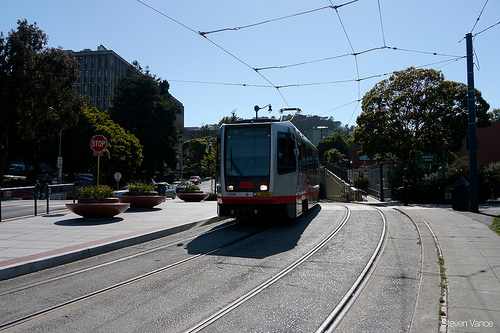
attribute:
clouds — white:
[170, 37, 237, 74]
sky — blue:
[121, 8, 496, 124]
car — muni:
[216, 118, 322, 220]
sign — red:
[92, 132, 106, 152]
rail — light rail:
[217, 111, 323, 226]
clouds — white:
[199, 100, 220, 110]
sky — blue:
[50, 5, 105, 34]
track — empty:
[185, 200, 387, 331]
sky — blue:
[46, 4, 498, 117]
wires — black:
[207, 7, 360, 77]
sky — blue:
[3, 0, 499, 127]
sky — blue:
[65, 13, 96, 38]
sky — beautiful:
[248, 16, 370, 69]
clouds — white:
[151, 41, 256, 118]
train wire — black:
[269, 57, 323, 74]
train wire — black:
[241, 15, 280, 35]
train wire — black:
[291, 75, 328, 90]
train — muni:
[221, 118, 305, 209]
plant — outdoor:
[72, 183, 112, 201]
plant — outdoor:
[127, 179, 152, 194]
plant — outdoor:
[175, 182, 200, 194]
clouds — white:
[84, 8, 128, 43]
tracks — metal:
[305, 208, 397, 318]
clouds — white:
[60, 9, 116, 47]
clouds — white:
[187, 49, 232, 75]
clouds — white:
[360, 22, 416, 47]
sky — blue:
[223, 31, 279, 76]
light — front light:
[223, 180, 269, 196]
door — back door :
[220, 120, 271, 195]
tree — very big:
[343, 64, 483, 213]